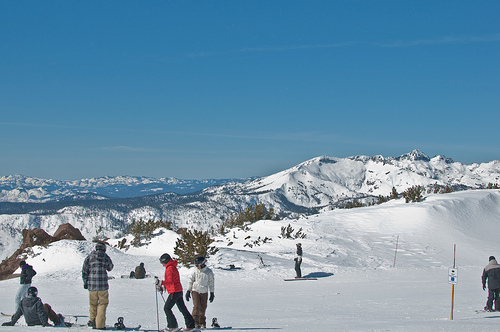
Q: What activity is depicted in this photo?
A: Skiing.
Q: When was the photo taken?
A: During the day.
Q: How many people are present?
A: Eight.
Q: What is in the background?
A: Mountains.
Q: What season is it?
A: Winter.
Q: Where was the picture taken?
A: On a ski slope.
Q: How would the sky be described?
A: Bright blue and clear.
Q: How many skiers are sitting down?
A: Two.